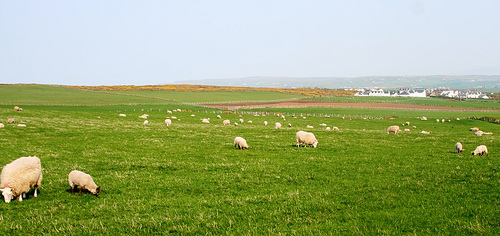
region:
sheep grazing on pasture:
[3, 3, 495, 229]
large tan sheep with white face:
[5, 153, 45, 205]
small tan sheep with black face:
[65, 166, 103, 199]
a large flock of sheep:
[140, 105, 493, 161]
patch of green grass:
[107, 160, 498, 230]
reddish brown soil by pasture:
[195, 96, 499, 114]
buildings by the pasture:
[355, 84, 491, 101]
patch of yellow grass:
[57, 82, 357, 98]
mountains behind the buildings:
[167, 71, 497, 90]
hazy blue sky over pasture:
[4, 4, 493, 71]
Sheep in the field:
[5, 102, 490, 204]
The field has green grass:
[8, 104, 493, 231]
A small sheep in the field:
[67, 168, 100, 195]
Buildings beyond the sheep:
[355, 88, 492, 100]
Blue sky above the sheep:
[1, 0, 499, 74]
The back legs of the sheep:
[66, 180, 74, 195]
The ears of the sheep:
[0, 183, 15, 190]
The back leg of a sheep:
[30, 185, 40, 197]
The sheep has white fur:
[0, 153, 40, 191]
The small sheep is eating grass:
[232, 134, 252, 149]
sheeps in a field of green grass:
[2, 85, 499, 217]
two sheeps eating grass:
[4, 150, 116, 223]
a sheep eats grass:
[283, 124, 332, 164]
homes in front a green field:
[347, 74, 497, 106]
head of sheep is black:
[91, 180, 102, 197]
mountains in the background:
[144, 64, 491, 94]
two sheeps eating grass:
[439, 136, 493, 164]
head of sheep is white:
[1, 179, 18, 206]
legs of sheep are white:
[15, 188, 48, 210]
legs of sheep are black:
[66, 185, 88, 200]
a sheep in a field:
[1, 152, 41, 202]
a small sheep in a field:
[66, 167, 99, 198]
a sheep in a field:
[292, 129, 318, 149]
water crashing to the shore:
[357, 85, 499, 97]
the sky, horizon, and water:
[1, 0, 498, 93]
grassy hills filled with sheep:
[0, 84, 499, 234]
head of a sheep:
[1, 186, 13, 204]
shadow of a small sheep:
[66, 185, 88, 195]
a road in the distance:
[210, 98, 499, 115]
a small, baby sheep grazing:
[62, 166, 110, 198]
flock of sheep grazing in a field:
[132, 93, 434, 176]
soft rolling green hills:
[8, 79, 433, 187]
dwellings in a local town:
[353, 77, 488, 114]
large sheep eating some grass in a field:
[0, 150, 47, 207]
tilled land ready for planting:
[211, 89, 485, 125]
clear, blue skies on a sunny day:
[6, 3, 486, 78]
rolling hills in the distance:
[188, 65, 493, 120]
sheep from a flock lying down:
[0, 112, 44, 132]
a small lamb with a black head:
[94, 184, 104, 196]